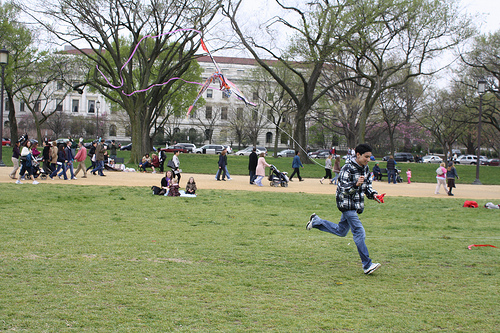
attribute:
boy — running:
[305, 136, 422, 295]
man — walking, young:
[214, 150, 240, 183]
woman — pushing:
[258, 148, 288, 187]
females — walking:
[428, 148, 468, 195]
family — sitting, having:
[152, 168, 247, 223]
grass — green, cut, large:
[85, 197, 199, 279]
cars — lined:
[110, 128, 284, 159]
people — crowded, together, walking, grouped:
[15, 135, 90, 192]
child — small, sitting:
[397, 163, 428, 190]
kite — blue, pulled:
[137, 25, 252, 109]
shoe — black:
[286, 196, 332, 239]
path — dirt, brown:
[207, 173, 293, 198]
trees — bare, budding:
[98, 3, 356, 104]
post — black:
[473, 87, 499, 188]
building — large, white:
[186, 47, 286, 130]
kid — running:
[210, 128, 445, 264]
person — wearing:
[69, 147, 96, 174]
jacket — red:
[75, 149, 117, 187]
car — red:
[159, 136, 202, 154]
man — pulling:
[262, 123, 375, 251]